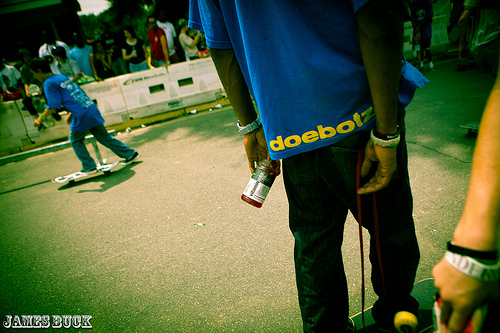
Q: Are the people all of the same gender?
A: No, they are both male and female.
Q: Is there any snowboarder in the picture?
A: No, there are no snowboarders.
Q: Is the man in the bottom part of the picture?
A: No, the man is in the top of the image.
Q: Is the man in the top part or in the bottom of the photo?
A: The man is in the top of the image.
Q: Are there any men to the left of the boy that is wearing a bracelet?
A: Yes, there is a man to the left of the boy.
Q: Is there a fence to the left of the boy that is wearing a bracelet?
A: No, there is a man to the left of the boy.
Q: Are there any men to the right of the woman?
A: Yes, there is a man to the right of the woman.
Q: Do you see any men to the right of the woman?
A: Yes, there is a man to the right of the woman.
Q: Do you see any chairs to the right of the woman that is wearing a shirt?
A: No, there is a man to the right of the woman.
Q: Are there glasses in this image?
A: No, there are no glasses.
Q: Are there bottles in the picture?
A: Yes, there is a bottle.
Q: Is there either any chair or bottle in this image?
A: Yes, there is a bottle.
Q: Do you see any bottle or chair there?
A: Yes, there is a bottle.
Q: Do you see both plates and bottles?
A: No, there is a bottle but no plates.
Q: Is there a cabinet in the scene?
A: No, there are no cabinets.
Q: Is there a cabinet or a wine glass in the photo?
A: No, there are no cabinets or wine glasses.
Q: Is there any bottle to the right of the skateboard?
A: Yes, there is a bottle to the right of the skateboard.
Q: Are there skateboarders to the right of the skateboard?
A: No, there is a bottle to the right of the skateboard.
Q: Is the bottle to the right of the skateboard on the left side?
A: Yes, the bottle is to the right of the skateboard.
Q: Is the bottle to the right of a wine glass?
A: No, the bottle is to the right of the skateboard.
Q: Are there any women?
A: Yes, there is a woman.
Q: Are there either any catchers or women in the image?
A: Yes, there is a woman.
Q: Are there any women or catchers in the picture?
A: Yes, there is a woman.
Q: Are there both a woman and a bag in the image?
A: No, there is a woman but no bags.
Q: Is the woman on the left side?
A: Yes, the woman is on the left of the image.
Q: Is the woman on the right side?
A: No, the woman is on the left of the image.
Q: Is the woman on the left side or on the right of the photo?
A: The woman is on the left of the image.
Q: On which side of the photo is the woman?
A: The woman is on the left of the image.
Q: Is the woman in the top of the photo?
A: Yes, the woman is in the top of the image.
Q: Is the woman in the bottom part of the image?
A: No, the woman is in the top of the image.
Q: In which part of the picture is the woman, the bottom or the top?
A: The woman is in the top of the image.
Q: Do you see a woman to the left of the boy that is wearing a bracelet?
A: Yes, there is a woman to the left of the boy.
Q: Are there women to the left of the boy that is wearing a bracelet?
A: Yes, there is a woman to the left of the boy.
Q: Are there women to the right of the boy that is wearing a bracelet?
A: No, the woman is to the left of the boy.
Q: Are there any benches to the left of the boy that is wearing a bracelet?
A: No, there is a woman to the left of the boy.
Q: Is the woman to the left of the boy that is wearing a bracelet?
A: Yes, the woman is to the left of the boy.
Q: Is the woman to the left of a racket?
A: No, the woman is to the left of the boy.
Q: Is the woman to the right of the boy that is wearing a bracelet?
A: No, the woman is to the left of the boy.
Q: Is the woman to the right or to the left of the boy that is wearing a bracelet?
A: The woman is to the left of the boy.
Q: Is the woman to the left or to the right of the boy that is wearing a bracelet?
A: The woman is to the left of the boy.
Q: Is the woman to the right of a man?
A: Yes, the woman is to the right of a man.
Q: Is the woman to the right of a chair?
A: No, the woman is to the right of a man.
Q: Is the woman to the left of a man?
A: No, the woman is to the right of a man.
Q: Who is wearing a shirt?
A: The woman is wearing a shirt.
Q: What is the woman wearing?
A: The woman is wearing a shirt.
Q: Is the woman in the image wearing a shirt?
A: Yes, the woman is wearing a shirt.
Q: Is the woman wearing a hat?
A: No, the woman is wearing a shirt.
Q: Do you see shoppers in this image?
A: No, there are no shoppers.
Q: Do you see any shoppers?
A: No, there are no shoppers.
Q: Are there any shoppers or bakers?
A: No, there are no shoppers or bakers.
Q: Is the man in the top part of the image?
A: Yes, the man is in the top of the image.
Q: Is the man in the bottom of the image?
A: No, the man is in the top of the image.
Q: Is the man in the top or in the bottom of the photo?
A: The man is in the top of the image.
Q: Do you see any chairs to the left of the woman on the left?
A: No, there is a man to the left of the woman.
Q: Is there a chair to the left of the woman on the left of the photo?
A: No, there is a man to the left of the woman.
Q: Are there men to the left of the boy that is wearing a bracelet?
A: Yes, there is a man to the left of the boy.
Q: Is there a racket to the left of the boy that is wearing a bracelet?
A: No, there is a man to the left of the boy.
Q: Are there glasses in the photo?
A: No, there are no glasses.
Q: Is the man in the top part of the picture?
A: Yes, the man is in the top of the image.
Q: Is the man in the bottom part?
A: No, the man is in the top of the image.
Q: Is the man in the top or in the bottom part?
A: The man is in the top of the image.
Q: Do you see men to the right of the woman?
A: Yes, there is a man to the right of the woman.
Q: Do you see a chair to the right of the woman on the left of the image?
A: No, there is a man to the right of the woman.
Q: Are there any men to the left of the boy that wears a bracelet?
A: Yes, there is a man to the left of the boy.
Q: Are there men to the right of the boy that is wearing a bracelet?
A: No, the man is to the left of the boy.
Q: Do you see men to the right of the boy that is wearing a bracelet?
A: No, the man is to the left of the boy.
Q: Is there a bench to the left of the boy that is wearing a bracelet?
A: No, there is a man to the left of the boy.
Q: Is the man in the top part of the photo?
A: Yes, the man is in the top of the image.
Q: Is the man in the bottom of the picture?
A: No, the man is in the top of the image.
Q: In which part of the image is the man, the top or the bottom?
A: The man is in the top of the image.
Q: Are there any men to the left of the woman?
A: Yes, there is a man to the left of the woman.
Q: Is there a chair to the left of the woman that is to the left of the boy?
A: No, there is a man to the left of the woman.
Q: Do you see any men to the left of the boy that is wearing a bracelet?
A: Yes, there is a man to the left of the boy.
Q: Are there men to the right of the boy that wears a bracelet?
A: No, the man is to the left of the boy.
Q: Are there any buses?
A: No, there are no buses.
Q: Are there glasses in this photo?
A: No, there are no glasses.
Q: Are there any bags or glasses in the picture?
A: No, there are no glasses or bags.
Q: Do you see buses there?
A: No, there are no buses.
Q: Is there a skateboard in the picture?
A: Yes, there is a skateboard.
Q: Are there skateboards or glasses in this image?
A: Yes, there is a skateboard.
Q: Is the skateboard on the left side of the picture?
A: Yes, the skateboard is on the left of the image.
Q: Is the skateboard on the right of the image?
A: No, the skateboard is on the left of the image.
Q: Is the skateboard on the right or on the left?
A: The skateboard is on the left of the image.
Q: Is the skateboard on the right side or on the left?
A: The skateboard is on the left of the image.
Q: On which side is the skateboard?
A: The skateboard is on the left of the image.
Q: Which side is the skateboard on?
A: The skateboard is on the left of the image.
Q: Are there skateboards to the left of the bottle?
A: Yes, there is a skateboard to the left of the bottle.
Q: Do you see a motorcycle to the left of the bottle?
A: No, there is a skateboard to the left of the bottle.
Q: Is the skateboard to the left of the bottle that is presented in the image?
A: Yes, the skateboard is to the left of the bottle.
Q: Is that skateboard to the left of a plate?
A: No, the skateboard is to the left of the bottle.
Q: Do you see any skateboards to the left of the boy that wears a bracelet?
A: Yes, there is a skateboard to the left of the boy.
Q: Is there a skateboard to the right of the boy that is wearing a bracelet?
A: No, the skateboard is to the left of the boy.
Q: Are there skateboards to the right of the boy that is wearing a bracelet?
A: No, the skateboard is to the left of the boy.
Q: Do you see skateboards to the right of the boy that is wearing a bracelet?
A: No, the skateboard is to the left of the boy.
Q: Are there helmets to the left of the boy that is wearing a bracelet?
A: No, there is a skateboard to the left of the boy.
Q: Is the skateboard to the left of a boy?
A: Yes, the skateboard is to the left of a boy.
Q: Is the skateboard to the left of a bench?
A: No, the skateboard is to the left of a boy.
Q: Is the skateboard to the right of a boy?
A: No, the skateboard is to the left of a boy.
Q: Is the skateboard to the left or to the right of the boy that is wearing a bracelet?
A: The skateboard is to the left of the boy.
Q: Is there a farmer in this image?
A: No, there are no farmers.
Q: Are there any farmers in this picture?
A: No, there are no farmers.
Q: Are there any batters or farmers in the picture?
A: No, there are no farmers or batters.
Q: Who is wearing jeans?
A: The boy is wearing jeans.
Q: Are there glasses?
A: No, there are no glasses.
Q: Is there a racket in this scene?
A: No, there are no rackets.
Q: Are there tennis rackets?
A: No, there are no tennis rackets.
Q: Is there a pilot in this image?
A: No, there are no pilots.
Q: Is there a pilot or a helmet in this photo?
A: No, there are no pilots or helmets.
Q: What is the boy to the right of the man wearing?
A: The boy is wearing a bracelet.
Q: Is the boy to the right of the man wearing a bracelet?
A: Yes, the boy is wearing a bracelet.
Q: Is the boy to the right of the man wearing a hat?
A: No, the boy is wearing a bracelet.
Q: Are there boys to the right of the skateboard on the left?
A: Yes, there is a boy to the right of the skateboard.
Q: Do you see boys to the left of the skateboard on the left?
A: No, the boy is to the right of the skateboard.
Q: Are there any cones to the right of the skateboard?
A: No, there is a boy to the right of the skateboard.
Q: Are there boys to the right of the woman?
A: Yes, there is a boy to the right of the woman.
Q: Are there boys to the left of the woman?
A: No, the boy is to the right of the woman.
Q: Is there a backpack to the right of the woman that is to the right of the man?
A: No, there is a boy to the right of the woman.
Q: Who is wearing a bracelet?
A: The boy is wearing a bracelet.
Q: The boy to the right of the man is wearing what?
A: The boy is wearing a bracelet.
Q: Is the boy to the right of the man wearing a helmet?
A: No, the boy is wearing a bracelet.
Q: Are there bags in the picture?
A: No, there are no bags.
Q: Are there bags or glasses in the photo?
A: No, there are no bags or glasses.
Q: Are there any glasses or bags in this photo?
A: No, there are no bags or glasses.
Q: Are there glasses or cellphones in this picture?
A: No, there are no glasses or cellphones.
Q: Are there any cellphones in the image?
A: No, there are no cellphones.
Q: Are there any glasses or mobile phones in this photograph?
A: No, there are no mobile phones or glasses.